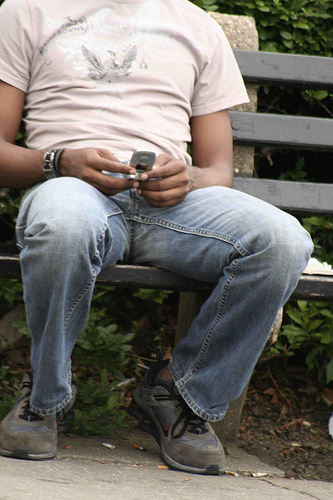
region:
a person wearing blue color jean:
[17, 191, 259, 426]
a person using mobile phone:
[121, 143, 153, 191]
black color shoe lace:
[171, 401, 208, 435]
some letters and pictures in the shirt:
[52, 10, 160, 90]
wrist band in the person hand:
[42, 145, 66, 176]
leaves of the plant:
[265, 5, 321, 45]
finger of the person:
[85, 150, 129, 196]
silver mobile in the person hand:
[125, 146, 155, 180]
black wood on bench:
[231, 47, 329, 87]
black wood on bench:
[227, 107, 331, 146]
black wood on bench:
[234, 175, 330, 212]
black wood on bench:
[293, 275, 330, 296]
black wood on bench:
[99, 263, 195, 289]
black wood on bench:
[1, 256, 22, 273]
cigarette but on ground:
[101, 440, 116, 450]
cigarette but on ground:
[130, 443, 144, 450]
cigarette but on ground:
[155, 462, 170, 470]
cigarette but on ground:
[223, 467, 239, 476]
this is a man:
[2, 8, 295, 474]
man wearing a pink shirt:
[3, 5, 254, 200]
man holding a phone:
[109, 131, 199, 223]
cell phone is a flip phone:
[106, 137, 163, 210]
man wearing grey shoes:
[8, 350, 254, 483]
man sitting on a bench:
[23, 9, 332, 324]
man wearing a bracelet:
[33, 143, 69, 181]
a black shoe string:
[159, 390, 212, 454]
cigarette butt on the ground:
[80, 417, 180, 493]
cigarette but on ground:
[63, 443, 74, 450]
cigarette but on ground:
[132, 441, 145, 451]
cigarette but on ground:
[155, 463, 169, 469]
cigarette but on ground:
[249, 467, 268, 479]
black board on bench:
[0, 257, 23, 270]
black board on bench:
[292, 273, 331, 295]